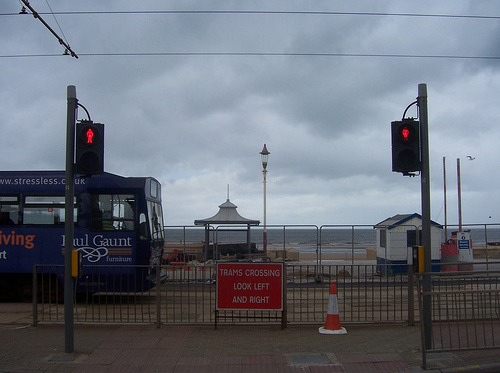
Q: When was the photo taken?
A: Daytime.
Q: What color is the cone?
A: Orange and white.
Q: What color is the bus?
A: Blue.